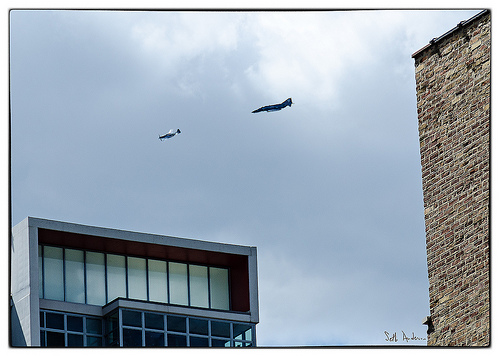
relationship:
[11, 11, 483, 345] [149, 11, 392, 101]
sky with clouds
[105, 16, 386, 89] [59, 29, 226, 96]
cloud going across sky.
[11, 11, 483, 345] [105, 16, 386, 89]
sky has cloud